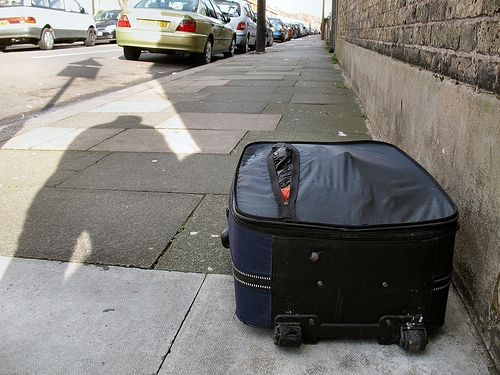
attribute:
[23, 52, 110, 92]
street — paved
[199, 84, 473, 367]
luggage — black, blue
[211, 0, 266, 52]
car — white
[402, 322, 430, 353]
wheel — black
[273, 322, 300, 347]
wheel — black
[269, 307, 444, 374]
wheels — black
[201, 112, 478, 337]
luggage — open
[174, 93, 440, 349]
luggage — blue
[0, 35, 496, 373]
sidewalk — brick, paved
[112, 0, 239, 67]
car — lime green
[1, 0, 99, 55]
mini van — white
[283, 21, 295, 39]
car — red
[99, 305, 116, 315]
spot — black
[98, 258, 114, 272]
spot — black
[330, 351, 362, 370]
spot — black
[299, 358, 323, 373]
spot — black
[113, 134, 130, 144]
spot — black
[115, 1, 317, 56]
cars — parked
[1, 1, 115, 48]
cars — parked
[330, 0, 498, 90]
brick wall — brown, bricked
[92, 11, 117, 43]
car — black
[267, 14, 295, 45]
car — blue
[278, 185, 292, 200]
object — red